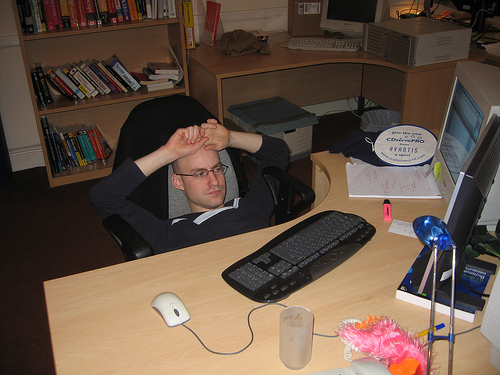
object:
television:
[429, 60, 498, 201]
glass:
[274, 304, 317, 373]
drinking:
[282, 307, 311, 328]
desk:
[43, 151, 499, 374]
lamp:
[409, 210, 462, 375]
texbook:
[398, 245, 493, 323]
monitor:
[419, 113, 499, 295]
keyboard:
[220, 208, 378, 305]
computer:
[396, 107, 499, 315]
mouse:
[148, 287, 194, 330]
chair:
[96, 92, 319, 264]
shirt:
[86, 132, 293, 258]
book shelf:
[12, 2, 191, 190]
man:
[85, 112, 295, 262]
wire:
[181, 301, 480, 356]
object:
[333, 315, 438, 374]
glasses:
[174, 162, 230, 180]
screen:
[439, 80, 483, 188]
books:
[104, 51, 144, 94]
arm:
[91, 144, 183, 253]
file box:
[228, 95, 319, 168]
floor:
[2, 106, 397, 374]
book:
[394, 242, 490, 323]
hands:
[167, 124, 211, 157]